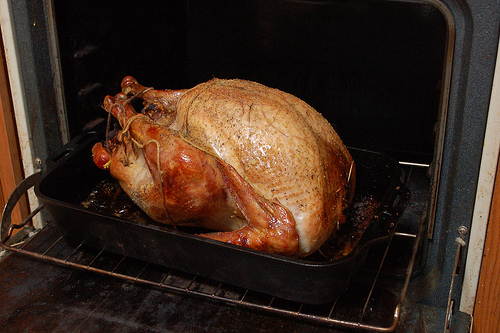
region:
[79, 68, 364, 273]
nicely browned trussed poultry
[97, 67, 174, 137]
trussed legs of cooked turkey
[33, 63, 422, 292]
cooked poultry in a pan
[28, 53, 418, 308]
roasting pan with turkey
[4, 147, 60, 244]
hinge of an open oven door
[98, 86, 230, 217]
roasted turkey drumstick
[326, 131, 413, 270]
roasting pan with poultry drippings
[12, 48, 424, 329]
roasting pan on oven rack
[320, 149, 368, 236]
toothpicks holding turkey skin shut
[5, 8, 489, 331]
open oven door with cooked food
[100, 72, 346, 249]
THAT IS A CHICKEN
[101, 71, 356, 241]
THE CHICKEN IS IN AN OVEN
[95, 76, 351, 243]
THE CHICKEN IS BIG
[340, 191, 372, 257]
THAT IS A TRAY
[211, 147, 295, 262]
THAT IS A CHICKEN WING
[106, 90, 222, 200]
THAT IS A DRUMSTICK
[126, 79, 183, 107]
THAT IS A DRUMSTICK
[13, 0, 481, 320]
THAT IS AN OVEN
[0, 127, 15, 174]
THAT IS A DOOR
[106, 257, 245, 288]
THAT IS A WIRE MESH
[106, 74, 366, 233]
a chicken being roasted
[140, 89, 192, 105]
that is a drumstick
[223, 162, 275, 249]
the wing of the chicken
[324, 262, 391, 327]
that is a roasting gauge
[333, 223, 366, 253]
that is a tray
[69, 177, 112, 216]
the tray is metallic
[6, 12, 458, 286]
the chicken is in an oven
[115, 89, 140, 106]
a string tying the chicken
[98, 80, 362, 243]
it is a big chicken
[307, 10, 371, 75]
this is the wall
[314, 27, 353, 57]
the wall is black in color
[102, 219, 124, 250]
this is a tray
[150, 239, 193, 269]
the tray is black in color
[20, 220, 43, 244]
this is a grill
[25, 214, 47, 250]
the grill is metallic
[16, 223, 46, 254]
the grill is rusty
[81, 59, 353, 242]
this is a chicken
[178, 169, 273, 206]
the meat is oily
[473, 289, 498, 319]
the wood is brown in color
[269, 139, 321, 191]
part of a chicken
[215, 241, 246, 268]
part of a tray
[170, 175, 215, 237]
part of a thigh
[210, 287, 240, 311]
part of a metal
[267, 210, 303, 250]
part of a thigh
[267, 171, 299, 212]
art of a dot